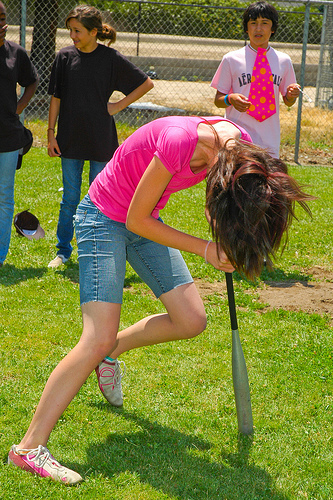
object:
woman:
[5, 112, 319, 489]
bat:
[223, 266, 255, 434]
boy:
[211, 0, 303, 165]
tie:
[245, 43, 278, 124]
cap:
[13, 209, 46, 244]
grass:
[0, 118, 332, 499]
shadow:
[0, 261, 36, 289]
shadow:
[55, 258, 146, 290]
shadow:
[229, 254, 315, 292]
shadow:
[53, 399, 289, 499]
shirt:
[45, 42, 149, 165]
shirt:
[0, 39, 38, 155]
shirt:
[88, 114, 253, 230]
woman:
[42, 3, 155, 273]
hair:
[202, 134, 318, 285]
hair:
[64, 2, 116, 48]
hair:
[239, 4, 278, 42]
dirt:
[188, 265, 332, 325]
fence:
[0, 1, 332, 169]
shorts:
[71, 190, 195, 306]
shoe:
[5, 440, 83, 487]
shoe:
[94, 352, 124, 410]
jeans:
[54, 154, 110, 262]